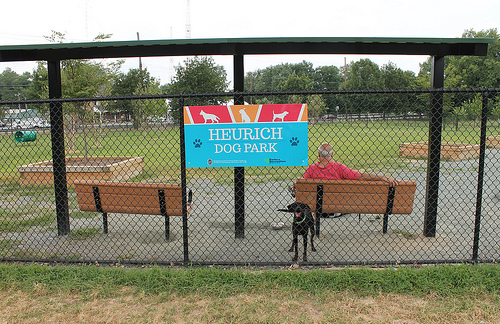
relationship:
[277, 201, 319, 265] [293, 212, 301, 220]
dog has tongue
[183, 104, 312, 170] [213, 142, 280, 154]
sign says dog park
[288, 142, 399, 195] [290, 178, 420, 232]
man on bench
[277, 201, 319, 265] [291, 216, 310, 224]
dog wearing collar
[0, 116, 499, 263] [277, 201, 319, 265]
park for dog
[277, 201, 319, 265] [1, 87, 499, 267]
dog behind fence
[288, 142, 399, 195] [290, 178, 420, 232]
man sitting on bench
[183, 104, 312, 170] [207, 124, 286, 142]
sign says heurich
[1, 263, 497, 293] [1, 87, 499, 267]
grass along fence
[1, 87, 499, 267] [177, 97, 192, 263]
fence has post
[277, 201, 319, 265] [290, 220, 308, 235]
dog has chest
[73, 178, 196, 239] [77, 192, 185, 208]
bench has slat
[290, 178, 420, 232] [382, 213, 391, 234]
bench has leg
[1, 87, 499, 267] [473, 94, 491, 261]
fence has post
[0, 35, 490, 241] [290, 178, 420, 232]
ramada over bench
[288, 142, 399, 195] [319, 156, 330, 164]
man has neck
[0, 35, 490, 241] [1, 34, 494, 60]
ramada has roof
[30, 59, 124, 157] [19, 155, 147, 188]
tree in planter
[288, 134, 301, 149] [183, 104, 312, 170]
icon on sign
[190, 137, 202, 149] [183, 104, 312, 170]
icon on sign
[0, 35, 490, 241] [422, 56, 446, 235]
ramada has post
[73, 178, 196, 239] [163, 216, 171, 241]
bench has leg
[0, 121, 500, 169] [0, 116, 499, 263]
grass in park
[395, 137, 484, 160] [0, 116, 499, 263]
planter in park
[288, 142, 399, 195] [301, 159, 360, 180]
man wearing shirt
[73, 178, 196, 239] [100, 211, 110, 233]
bench has leg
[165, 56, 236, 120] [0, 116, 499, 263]
tree in park